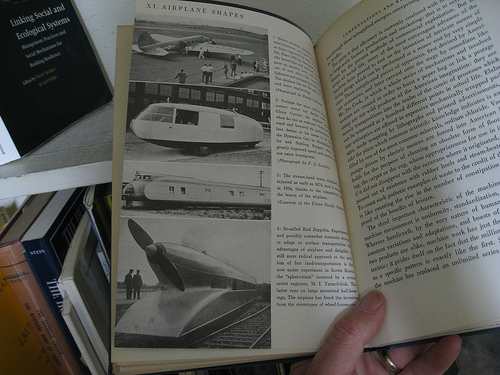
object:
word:
[312, 202, 323, 207]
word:
[375, 11, 392, 24]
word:
[403, 51, 425, 67]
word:
[281, 98, 295, 106]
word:
[302, 95, 312, 102]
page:
[111, 0, 371, 362]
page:
[314, 0, 500, 346]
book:
[107, 1, 500, 375]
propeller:
[128, 219, 186, 292]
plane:
[116, 218, 260, 348]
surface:
[0, 97, 134, 177]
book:
[20, 185, 87, 373]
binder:
[3, 192, 114, 374]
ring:
[374, 348, 400, 374]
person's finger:
[372, 335, 457, 372]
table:
[0, 79, 125, 201]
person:
[231, 59, 237, 76]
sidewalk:
[203, 69, 268, 85]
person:
[207, 63, 214, 82]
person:
[175, 69, 188, 85]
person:
[223, 60, 228, 78]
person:
[255, 58, 260, 72]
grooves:
[336, 322, 355, 338]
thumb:
[301, 290, 385, 375]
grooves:
[342, 317, 355, 334]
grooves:
[333, 325, 344, 340]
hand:
[305, 291, 463, 374]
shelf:
[0, 182, 112, 374]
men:
[126, 268, 143, 301]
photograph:
[113, 217, 272, 350]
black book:
[0, 3, 114, 165]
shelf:
[0, 0, 116, 200]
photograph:
[127, 11, 270, 89]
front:
[0, 157, 114, 199]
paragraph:
[363, 181, 499, 289]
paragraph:
[275, 226, 359, 307]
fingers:
[361, 336, 463, 375]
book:
[2, 191, 86, 370]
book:
[61, 212, 110, 372]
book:
[60, 258, 107, 374]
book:
[82, 185, 112, 277]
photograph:
[123, 81, 270, 167]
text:
[275, 38, 359, 307]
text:
[147, 3, 244, 20]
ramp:
[190, 63, 268, 87]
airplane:
[132, 31, 253, 60]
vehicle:
[130, 102, 264, 155]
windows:
[175, 109, 200, 124]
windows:
[221, 112, 235, 127]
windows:
[138, 104, 174, 122]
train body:
[117, 237, 258, 347]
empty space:
[0, 0, 113, 175]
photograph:
[119, 159, 271, 220]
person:
[289, 290, 461, 375]